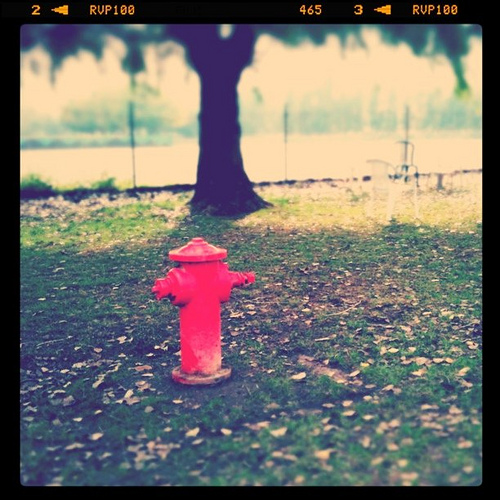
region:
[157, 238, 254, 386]
a fire hydrant is on the grass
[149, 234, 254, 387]
the hydrant is red in color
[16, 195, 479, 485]
the grass is a dark green color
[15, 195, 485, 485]
dry leaves are on the ground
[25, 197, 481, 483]
the dry leaves are brown in color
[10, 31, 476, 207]
a large tree is seen in the background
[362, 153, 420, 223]
a white chair is on the grass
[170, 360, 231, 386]
the base of the hydrant is rusty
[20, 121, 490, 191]
a lake is seen in the background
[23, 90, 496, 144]
vegetation is seen behind the lake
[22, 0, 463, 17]
black border & number line on old—or faux old—film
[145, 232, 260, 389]
supersaturated pinky red hydrant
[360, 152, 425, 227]
white plastic throwaway outdoor chair in middle distance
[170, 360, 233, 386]
muddy base of hydrant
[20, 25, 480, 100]
colorized green leaves blurry at top of shot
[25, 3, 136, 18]
2 ? RVP100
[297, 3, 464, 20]
465 3 ? RVP100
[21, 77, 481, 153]
blurry bushes in the far far distance turning blue green from coloring process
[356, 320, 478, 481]
green grass with brown leaves, focussed in mid-ground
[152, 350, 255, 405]
grassless, leafless mud circle around base of hydrant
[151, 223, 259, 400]
red metal fire hydrant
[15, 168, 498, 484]
brown dead leaves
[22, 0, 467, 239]
green tree in background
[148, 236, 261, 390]
fire hydrant on green grass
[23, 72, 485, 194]
black metal link fence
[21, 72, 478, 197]
metal fence behind tree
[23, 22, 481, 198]
green bushes behind fence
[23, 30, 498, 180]
white bright clear sky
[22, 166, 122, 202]
green bushes at edge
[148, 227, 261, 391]
old red fire hydrant on cement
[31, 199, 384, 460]
an orange fire hydrant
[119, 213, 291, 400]
a dark pink fire hydrant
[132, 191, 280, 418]
a hydrant on a small pedestal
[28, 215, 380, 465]
a hydrant surrounded by a square outline in the grass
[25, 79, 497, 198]
an out of focus fence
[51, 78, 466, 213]
a fence in the background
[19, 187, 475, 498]
ground covered with leaves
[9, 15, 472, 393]
early fall with leaves on the tree and on the ground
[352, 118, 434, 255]
a device holding a bag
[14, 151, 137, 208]
weeds in the fence line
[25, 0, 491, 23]
letters and numbers identifying this photo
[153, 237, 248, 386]
red fire hydrant in a field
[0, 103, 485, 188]
blurred fence behind large tree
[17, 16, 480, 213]
truck and lower boughs of a large tree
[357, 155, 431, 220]
white plastic garden chair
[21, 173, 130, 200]
weeds growing against chain link fence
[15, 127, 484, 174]
body of murky water behind fence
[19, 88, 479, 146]
blurred background of trees and brush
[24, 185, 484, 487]
grassy field with fallen leaves strewn over it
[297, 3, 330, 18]
yellow numbers "465"